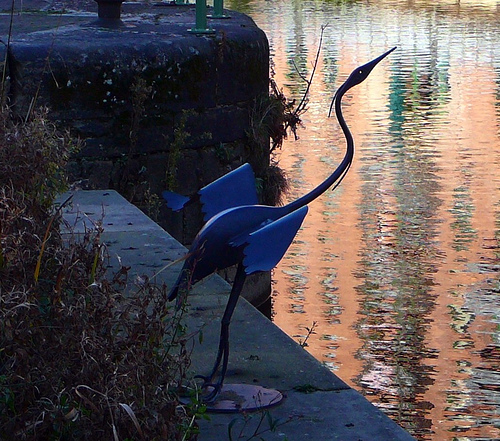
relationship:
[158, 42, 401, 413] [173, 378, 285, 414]
statue on base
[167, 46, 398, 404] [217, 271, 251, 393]
bird has leg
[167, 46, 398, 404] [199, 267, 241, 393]
bird has leg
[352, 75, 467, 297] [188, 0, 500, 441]
reflections on reflections